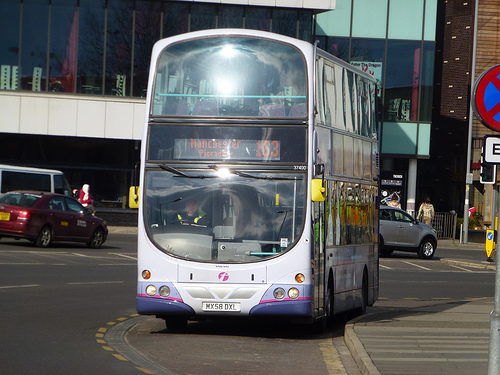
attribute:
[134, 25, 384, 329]
bus — two story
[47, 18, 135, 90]
window — glass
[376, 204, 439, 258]
car — grey